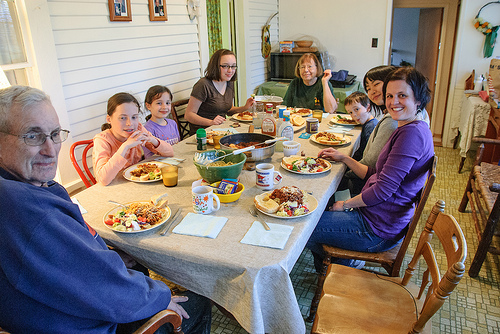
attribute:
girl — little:
[147, 85, 177, 145]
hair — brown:
[145, 83, 172, 95]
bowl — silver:
[216, 130, 280, 162]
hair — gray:
[4, 85, 45, 112]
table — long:
[62, 86, 369, 332]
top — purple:
[359, 119, 435, 240]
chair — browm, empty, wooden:
[307, 198, 469, 333]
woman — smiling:
[203, 43, 245, 102]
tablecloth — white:
[55, 104, 379, 329]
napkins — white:
[169, 208, 229, 240]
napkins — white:
[238, 217, 292, 252]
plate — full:
[249, 184, 319, 220]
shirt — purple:
[359, 114, 439, 237]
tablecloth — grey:
[68, 100, 361, 332]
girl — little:
[93, 90, 178, 187]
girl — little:
[144, 83, 184, 151]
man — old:
[4, 87, 205, 332]